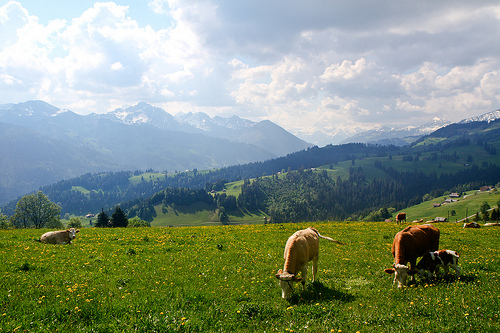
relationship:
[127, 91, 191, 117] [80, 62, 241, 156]
snow on mountain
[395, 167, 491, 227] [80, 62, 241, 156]
houses on mountain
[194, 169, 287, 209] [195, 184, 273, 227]
trees with leaves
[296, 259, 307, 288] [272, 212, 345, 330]
ear of cow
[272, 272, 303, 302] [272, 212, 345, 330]
head of cow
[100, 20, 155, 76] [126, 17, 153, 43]
cloud in sky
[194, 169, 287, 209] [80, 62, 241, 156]
trees in mountain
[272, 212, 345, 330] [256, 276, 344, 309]
cow on ground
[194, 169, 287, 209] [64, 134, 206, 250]
trees has hill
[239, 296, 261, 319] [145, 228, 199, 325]
shadow on grass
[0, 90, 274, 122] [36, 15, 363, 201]
mountains in background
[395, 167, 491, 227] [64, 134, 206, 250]
houses on hill